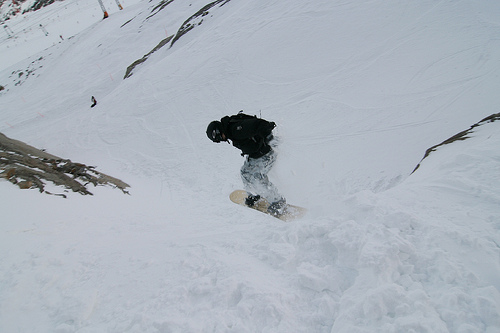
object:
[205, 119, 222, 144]
helmet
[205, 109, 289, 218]
man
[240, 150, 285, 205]
pants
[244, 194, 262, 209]
boot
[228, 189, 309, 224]
snowboard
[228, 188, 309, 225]
board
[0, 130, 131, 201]
rocks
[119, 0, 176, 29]
rocks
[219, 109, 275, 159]
gear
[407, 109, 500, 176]
rock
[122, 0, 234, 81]
rock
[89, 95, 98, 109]
snowboarder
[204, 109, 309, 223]
snowboarding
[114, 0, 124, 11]
post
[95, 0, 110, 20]
post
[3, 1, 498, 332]
snow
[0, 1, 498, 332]
ground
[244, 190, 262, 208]
foot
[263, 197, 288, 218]
foot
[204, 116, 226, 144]
head